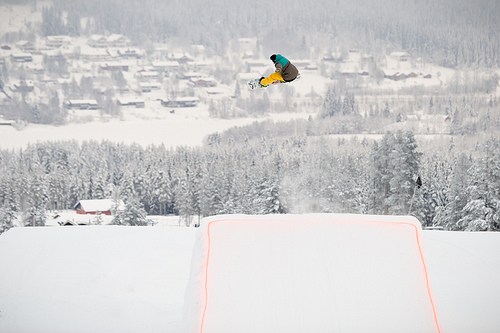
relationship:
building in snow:
[71, 191, 125, 222] [2, 111, 269, 145]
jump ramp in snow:
[187, 211, 449, 331] [0, 214, 499, 332]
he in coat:
[256, 53, 298, 89] [266, 51, 308, 99]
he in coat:
[256, 53, 298, 89] [274, 53, 296, 78]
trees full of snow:
[122, 141, 352, 211] [291, 162, 349, 196]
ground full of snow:
[0, 209, 499, 330] [35, 234, 120, 311]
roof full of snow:
[75, 198, 115, 212] [75, 196, 124, 225]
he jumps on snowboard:
[256, 53, 298, 89] [246, 59, 271, 101]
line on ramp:
[406, 221, 447, 331] [182, 186, 406, 328]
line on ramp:
[203, 209, 419, 230] [182, 186, 406, 328]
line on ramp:
[194, 214, 218, 331] [182, 186, 406, 328]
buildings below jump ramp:
[0, 10, 462, 226] [193, 211, 450, 333]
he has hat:
[256, 53, 298, 89] [266, 48, 277, 63]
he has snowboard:
[256, 53, 298, 89] [243, 77, 270, 89]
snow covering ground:
[41, 226, 161, 321] [141, 240, 193, 329]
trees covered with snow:
[10, 137, 480, 200] [2, 1, 497, 328]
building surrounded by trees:
[73, 199, 125, 216] [78, 121, 352, 191]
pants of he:
[255, 73, 292, 88] [256, 53, 298, 89]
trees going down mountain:
[1, 2, 498, 232] [0, 211, 498, 331]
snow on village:
[2, 1, 497, 328] [19, 28, 447, 119]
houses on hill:
[79, 28, 175, 73] [1, 32, 226, 126]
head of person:
[261, 53, 283, 60] [257, 53, 295, 88]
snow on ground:
[2, 1, 497, 328] [382, 117, 414, 147]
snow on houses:
[253, 233, 368, 311] [0, 27, 440, 212]